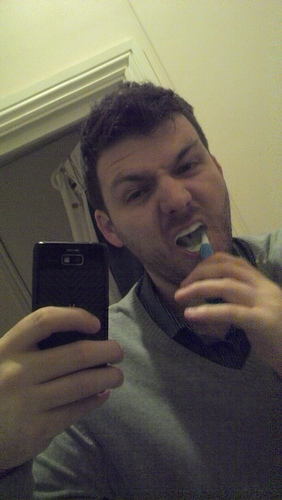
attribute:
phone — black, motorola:
[24, 229, 116, 366]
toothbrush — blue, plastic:
[190, 231, 219, 273]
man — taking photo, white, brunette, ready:
[26, 77, 280, 431]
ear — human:
[89, 201, 122, 250]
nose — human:
[154, 175, 198, 223]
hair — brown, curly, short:
[71, 73, 198, 144]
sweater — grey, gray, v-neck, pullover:
[32, 234, 277, 499]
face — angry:
[101, 135, 237, 285]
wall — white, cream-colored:
[4, 4, 279, 211]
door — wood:
[2, 45, 174, 178]